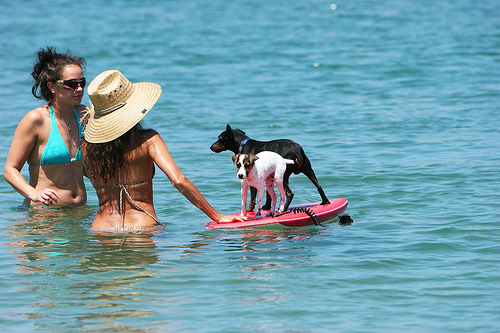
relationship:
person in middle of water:
[80, 70, 247, 233] [1, 1, 499, 331]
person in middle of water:
[4, 46, 88, 207] [1, 1, 499, 331]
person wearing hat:
[80, 70, 247, 233] [82, 69, 163, 145]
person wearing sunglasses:
[4, 46, 88, 207] [53, 77, 86, 91]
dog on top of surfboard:
[231, 151, 297, 219] [204, 196, 348, 231]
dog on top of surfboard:
[208, 123, 331, 212] [204, 196, 348, 231]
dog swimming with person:
[231, 151, 297, 219] [80, 70, 247, 233]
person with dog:
[80, 70, 247, 233] [231, 151, 297, 219]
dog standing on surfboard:
[208, 123, 331, 212] [204, 196, 348, 231]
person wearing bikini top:
[4, 46, 88, 207] [28, 106, 84, 167]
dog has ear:
[231, 151, 297, 219] [247, 153, 259, 164]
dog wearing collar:
[208, 123, 331, 212] [237, 136, 252, 154]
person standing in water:
[80, 70, 247, 233] [1, 1, 499, 331]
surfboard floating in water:
[204, 196, 348, 231] [1, 1, 499, 331]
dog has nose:
[231, 151, 297, 219] [238, 173, 244, 179]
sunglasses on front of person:
[53, 77, 86, 91] [4, 46, 88, 207]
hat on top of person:
[82, 69, 163, 145] [80, 70, 247, 233]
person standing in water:
[4, 46, 88, 207] [1, 1, 499, 331]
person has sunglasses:
[4, 46, 88, 207] [53, 77, 86, 91]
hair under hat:
[81, 122, 144, 183] [82, 69, 163, 145]